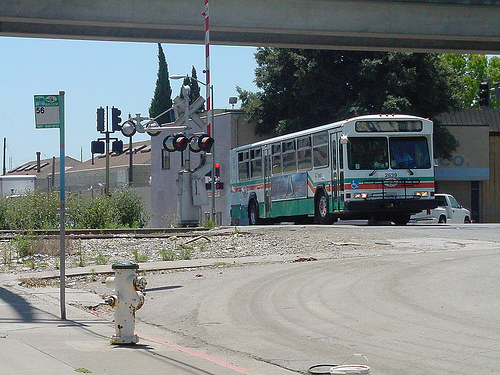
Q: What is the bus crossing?
A: Railroad tracks.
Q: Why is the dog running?
A: No dog.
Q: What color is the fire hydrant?
A: White.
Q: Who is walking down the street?
A: No one.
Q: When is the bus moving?
A: Now.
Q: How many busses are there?
A: One.